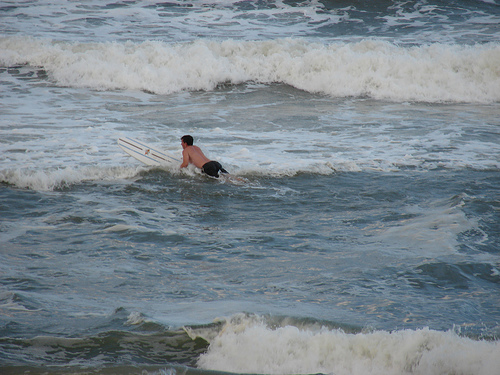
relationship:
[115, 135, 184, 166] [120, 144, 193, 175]
surfboard has stripe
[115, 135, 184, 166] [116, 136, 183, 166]
surfboard has stripe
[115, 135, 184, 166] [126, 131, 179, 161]
surfboard has stripe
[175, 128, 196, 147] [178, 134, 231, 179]
hair on surfer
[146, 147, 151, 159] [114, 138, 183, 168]
logo on boad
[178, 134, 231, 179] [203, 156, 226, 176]
surfer wearing shorts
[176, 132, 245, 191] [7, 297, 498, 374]
surfer paddling out into wave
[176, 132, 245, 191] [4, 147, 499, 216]
surfer paddling out into wave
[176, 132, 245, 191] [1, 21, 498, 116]
surfer paddling out into wave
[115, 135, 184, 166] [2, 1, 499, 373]
surfboard sticking out of water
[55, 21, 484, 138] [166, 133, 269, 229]
wave behind surfer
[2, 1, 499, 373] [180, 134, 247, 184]
water beneath surfer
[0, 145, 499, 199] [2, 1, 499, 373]
wave in water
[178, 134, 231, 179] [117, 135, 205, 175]
surfer on board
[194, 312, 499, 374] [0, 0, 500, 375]
bubbles and bubbles on water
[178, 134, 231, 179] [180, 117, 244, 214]
surfer not wearing a shirt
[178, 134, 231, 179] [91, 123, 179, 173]
surfer laying on board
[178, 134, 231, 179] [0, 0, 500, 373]
surfer surfing in ocean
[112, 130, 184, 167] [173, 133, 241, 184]
surfboard beneath man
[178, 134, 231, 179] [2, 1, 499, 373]
surfer in water